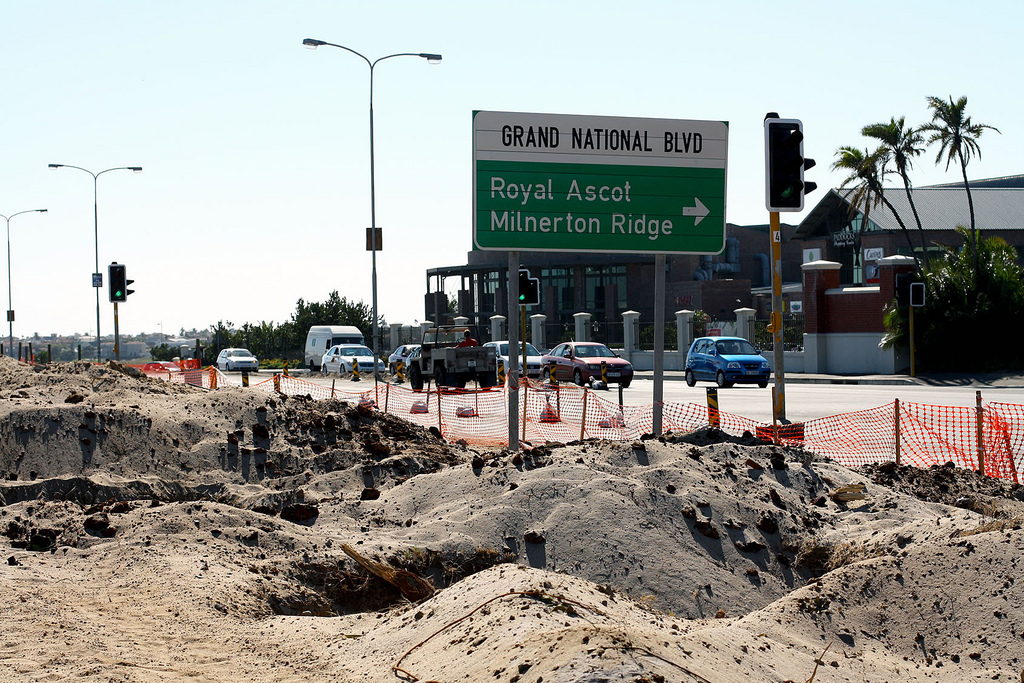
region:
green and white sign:
[469, 107, 727, 251]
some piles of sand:
[5, 355, 1021, 679]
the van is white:
[307, 322, 361, 367]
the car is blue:
[684, 333, 771, 390]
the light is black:
[108, 264, 131, 303]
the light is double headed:
[46, 161, 139, 355]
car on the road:
[217, 350, 256, 371]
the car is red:
[544, 343, 630, 386]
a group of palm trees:
[830, 94, 1004, 256]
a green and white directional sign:
[471, 108, 731, 260]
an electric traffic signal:
[764, 115, 818, 210]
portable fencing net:
[107, 356, 1022, 483]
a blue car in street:
[686, 331, 767, 390]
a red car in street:
[541, 339, 633, 387]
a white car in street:
[484, 337, 546, 382]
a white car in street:
[217, 346, 257, 370]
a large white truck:
[303, 323, 365, 372]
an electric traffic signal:
[104, 261, 134, 303]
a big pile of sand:
[537, 451, 940, 680]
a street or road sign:
[464, 104, 739, 449]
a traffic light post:
[758, 105, 819, 454]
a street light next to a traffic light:
[47, 146, 149, 371]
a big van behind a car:
[299, 320, 391, 382]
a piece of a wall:
[802, 253, 929, 386]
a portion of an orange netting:
[522, 379, 1020, 477]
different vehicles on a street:
[307, 315, 775, 405]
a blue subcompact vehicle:
[679, 332, 782, 389]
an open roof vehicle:
[404, 322, 504, 393]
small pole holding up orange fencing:
[886, 393, 902, 458]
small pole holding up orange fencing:
[768, 406, 791, 454]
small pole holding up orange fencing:
[574, 381, 590, 445]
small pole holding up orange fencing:
[512, 371, 525, 439]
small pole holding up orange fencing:
[427, 378, 446, 436]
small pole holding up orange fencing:
[381, 365, 386, 416]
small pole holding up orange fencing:
[324, 371, 337, 397]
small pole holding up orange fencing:
[269, 359, 289, 389]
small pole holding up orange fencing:
[201, 357, 211, 402]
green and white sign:
[462, 106, 738, 256]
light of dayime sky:
[1, 3, 1022, 337]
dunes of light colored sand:
[2, 352, 1021, 679]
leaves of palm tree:
[918, 94, 1004, 238]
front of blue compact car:
[686, 336, 769, 384]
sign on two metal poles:
[475, 110, 728, 437]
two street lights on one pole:
[302, 34, 439, 380]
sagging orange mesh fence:
[157, 364, 1021, 482]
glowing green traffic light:
[106, 263, 133, 301]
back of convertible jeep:
[409, 326, 492, 390]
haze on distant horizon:
[0, 332, 190, 364]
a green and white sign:
[481, 158, 723, 251]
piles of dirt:
[1, 332, 924, 678]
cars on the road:
[203, 300, 785, 425]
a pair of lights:
[285, 19, 466, 92]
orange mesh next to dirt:
[216, 329, 986, 485]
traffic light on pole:
[739, 89, 838, 413]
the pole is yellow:
[755, 209, 817, 456]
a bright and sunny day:
[29, 16, 1019, 659]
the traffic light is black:
[756, 75, 823, 234]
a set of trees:
[809, 72, 999, 253]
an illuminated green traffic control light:
[107, 259, 134, 308]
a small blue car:
[679, 331, 771, 390]